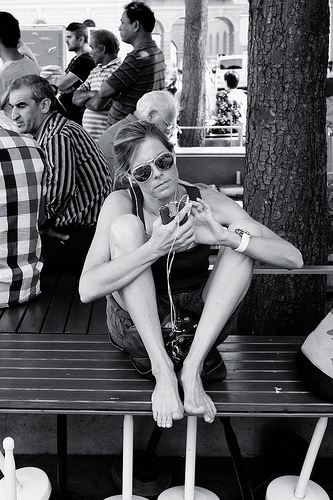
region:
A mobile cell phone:
[159, 198, 189, 226]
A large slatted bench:
[2, 329, 331, 412]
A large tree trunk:
[243, 0, 328, 265]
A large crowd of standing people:
[0, 2, 166, 140]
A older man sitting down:
[96, 90, 182, 187]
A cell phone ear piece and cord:
[129, 174, 190, 323]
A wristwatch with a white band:
[235, 229, 250, 251]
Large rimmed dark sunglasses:
[124, 150, 174, 182]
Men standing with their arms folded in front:
[50, 4, 167, 139]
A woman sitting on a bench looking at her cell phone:
[79, 121, 303, 425]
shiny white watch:
[228, 222, 252, 257]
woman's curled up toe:
[186, 402, 207, 424]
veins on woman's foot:
[162, 387, 184, 409]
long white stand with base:
[293, 420, 316, 498]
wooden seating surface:
[11, 337, 100, 385]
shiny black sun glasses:
[119, 147, 194, 184]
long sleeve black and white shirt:
[44, 126, 83, 187]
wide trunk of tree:
[241, 35, 329, 124]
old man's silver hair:
[132, 89, 184, 118]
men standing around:
[45, 5, 172, 130]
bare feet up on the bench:
[129, 362, 228, 445]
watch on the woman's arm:
[233, 227, 252, 254]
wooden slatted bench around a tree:
[10, 338, 84, 401]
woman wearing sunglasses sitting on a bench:
[115, 125, 183, 197]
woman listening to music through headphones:
[119, 170, 201, 349]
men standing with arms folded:
[62, 15, 171, 98]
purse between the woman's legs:
[117, 295, 239, 373]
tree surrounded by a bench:
[235, 19, 331, 247]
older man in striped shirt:
[4, 83, 99, 228]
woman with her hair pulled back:
[108, 122, 187, 209]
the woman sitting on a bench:
[78, 120, 302, 426]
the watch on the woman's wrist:
[231, 227, 251, 252]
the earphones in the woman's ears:
[126, 155, 189, 329]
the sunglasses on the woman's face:
[120, 152, 173, 181]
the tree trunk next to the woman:
[235, 0, 329, 332]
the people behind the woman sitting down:
[0, 2, 246, 310]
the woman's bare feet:
[150, 370, 216, 428]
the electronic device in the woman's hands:
[159, 200, 187, 226]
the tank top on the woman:
[127, 184, 209, 294]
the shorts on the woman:
[104, 292, 244, 354]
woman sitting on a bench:
[76, 125, 302, 425]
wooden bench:
[3, 312, 330, 420]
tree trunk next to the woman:
[240, 3, 324, 322]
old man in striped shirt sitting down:
[9, 76, 113, 267]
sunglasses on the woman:
[130, 152, 171, 181]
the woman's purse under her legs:
[122, 315, 223, 380]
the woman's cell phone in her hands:
[157, 203, 187, 225]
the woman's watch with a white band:
[234, 229, 250, 252]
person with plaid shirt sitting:
[0, 119, 44, 309]